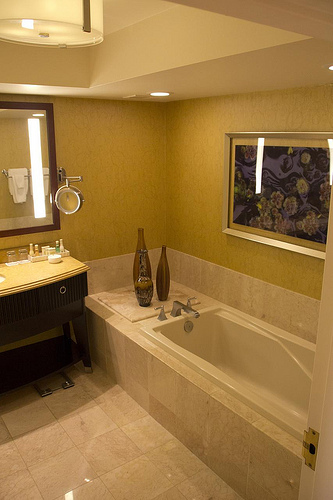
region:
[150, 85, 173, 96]
A light on the ceiling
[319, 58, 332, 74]
A light on the ceiling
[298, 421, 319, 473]
A door striking plate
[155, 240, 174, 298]
A tall brown vase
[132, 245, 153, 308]
A tall brown vase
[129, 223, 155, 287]
A tall brown vase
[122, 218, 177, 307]
A collection of decorations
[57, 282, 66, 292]
A silver handle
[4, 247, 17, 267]
A clear glass on the counter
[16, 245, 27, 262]
A clear glass on the counter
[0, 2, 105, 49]
Round light hanging from the ceiling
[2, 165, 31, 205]
Reflection of towels hanging on a rack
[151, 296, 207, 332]
Silver bathtub faucet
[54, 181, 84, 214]
Round bathroom mirror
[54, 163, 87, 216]
Bathroom mirror mounted to the wall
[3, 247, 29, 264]
Two clear glasses on the counter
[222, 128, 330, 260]
Flowered print hanging on the wall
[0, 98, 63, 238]
Wood framed mirror on the wall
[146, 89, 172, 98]
Round light in the ceiling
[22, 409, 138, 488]
Beige tile on bathroom floor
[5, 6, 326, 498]
Picture taken in a bathroom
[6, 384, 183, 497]
Floor made of tile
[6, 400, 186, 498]
The tiles are square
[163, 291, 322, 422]
A bath tub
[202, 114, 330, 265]
A picture on the wall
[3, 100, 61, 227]
A mirror on the wall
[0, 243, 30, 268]
Two glasses on the counter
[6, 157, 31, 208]
Towels reflected in the mirror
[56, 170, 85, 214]
Small mirror next to the big mirror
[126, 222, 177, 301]
Three glass bottles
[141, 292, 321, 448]
bathtub is color tan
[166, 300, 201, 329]
the faucet of bathtub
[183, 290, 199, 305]
right handle of faucet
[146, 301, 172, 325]
left handle of faucet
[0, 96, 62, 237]
mirror with brown frame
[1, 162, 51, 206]
towels reflected on mirror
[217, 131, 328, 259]
a picture in the wall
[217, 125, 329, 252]
picture has yellow border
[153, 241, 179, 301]
the bottle is color brown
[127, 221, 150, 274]
the bottle is color brown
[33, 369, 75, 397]
bathroom scale on the floor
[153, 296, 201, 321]
silver bathtub faucet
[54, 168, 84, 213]
round mirror attached to the wall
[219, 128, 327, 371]
framed artwork above the bathtub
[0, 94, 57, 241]
mirror attached to the wall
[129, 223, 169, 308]
three decorative vases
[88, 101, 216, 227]
yellow bathroom wall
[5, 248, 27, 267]
two upside down glasses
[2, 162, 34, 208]
white towels hanging on silver bars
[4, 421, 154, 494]
shiny bathroom floor